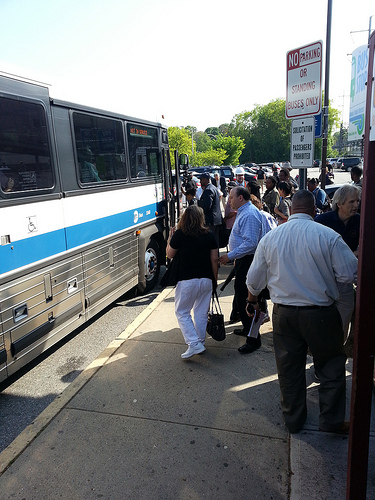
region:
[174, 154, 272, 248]
people getting in the bus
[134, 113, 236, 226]
people getting in the bus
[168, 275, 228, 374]
the pants are white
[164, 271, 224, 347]
the pants are white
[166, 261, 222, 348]
the pants are white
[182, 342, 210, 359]
the shoes are white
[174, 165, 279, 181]
the cars are parked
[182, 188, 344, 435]
the people are standing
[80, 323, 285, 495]
cracks in the sidewalk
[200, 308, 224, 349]
the bag is black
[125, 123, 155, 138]
screen on the bus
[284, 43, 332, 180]
signs on the post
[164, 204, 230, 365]
a short woman in white pants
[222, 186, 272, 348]
an old fat man in a button down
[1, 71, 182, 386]
a white and blue bus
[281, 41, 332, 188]
a tall no parking sign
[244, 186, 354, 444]
a short fat guy in business clothes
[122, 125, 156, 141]
a screen with a destination name on it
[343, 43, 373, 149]
a sign that says bus stop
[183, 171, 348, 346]
a crowd of people gather to get on a bus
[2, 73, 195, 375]
a bus pulls into a bus stop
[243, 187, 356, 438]
person standing on sidewalk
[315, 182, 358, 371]
person standing on sidewalk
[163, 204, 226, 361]
person standing on sidewalk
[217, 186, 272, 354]
person standing on sidewalk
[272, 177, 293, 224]
person standing on sidewalk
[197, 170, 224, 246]
person standing on sidewalk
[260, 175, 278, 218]
person standing on sidewalk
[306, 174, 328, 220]
person standing on sidewalk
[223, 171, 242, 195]
person standing on sidewalk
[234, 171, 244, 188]
person standing on sidewalk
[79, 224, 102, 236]
BLUE STRIPE ON THE BUS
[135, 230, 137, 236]
YELLOW LIGHT ON THE BUS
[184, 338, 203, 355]
WOMAN HAS ON WHITE SHOES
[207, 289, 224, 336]
WOMAN CARRYING A HANDBAG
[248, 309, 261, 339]
MAN HOLDING PAPERS IN HAND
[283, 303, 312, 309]
MAN WEARING A BELT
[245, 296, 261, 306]
MAN HAS A WATCH ON WRIST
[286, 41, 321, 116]
NO PARKING SIGN ON THE POLE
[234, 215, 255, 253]
MAN HAS ON A CHECKER SHIRT